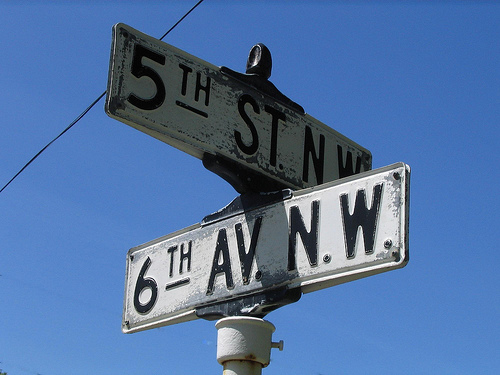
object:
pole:
[214, 315, 283, 374]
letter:
[133, 182, 384, 314]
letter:
[128, 43, 362, 179]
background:
[0, 0, 499, 373]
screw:
[272, 340, 284, 351]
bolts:
[384, 239, 393, 248]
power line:
[0, 0, 204, 190]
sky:
[1, 1, 499, 375]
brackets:
[200, 152, 293, 226]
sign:
[104, 21, 411, 334]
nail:
[279, 164, 283, 170]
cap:
[246, 42, 273, 79]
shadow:
[239, 189, 302, 303]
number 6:
[133, 256, 158, 315]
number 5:
[127, 43, 167, 111]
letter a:
[205, 228, 234, 296]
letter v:
[234, 216, 262, 284]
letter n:
[287, 199, 320, 271]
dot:
[255, 271, 263, 280]